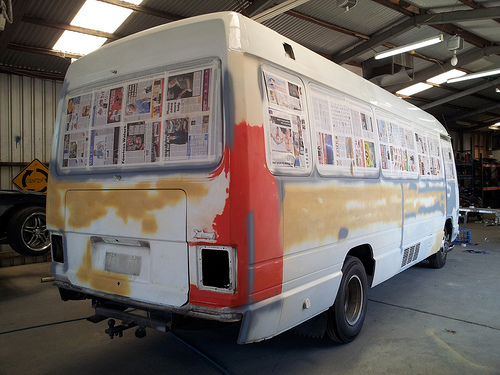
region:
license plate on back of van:
[98, 241, 154, 288]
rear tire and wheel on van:
[328, 239, 379, 351]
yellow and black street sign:
[11, 148, 66, 203]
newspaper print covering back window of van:
[58, 77, 239, 185]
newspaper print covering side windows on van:
[251, 58, 474, 203]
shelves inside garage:
[448, 116, 499, 207]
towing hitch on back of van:
[79, 298, 179, 354]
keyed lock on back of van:
[98, 160, 138, 198]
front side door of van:
[432, 106, 469, 256]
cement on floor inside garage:
[392, 281, 485, 373]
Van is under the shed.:
[45, 51, 437, 321]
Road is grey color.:
[387, 299, 464, 369]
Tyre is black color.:
[316, 253, 375, 348]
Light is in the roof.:
[359, 31, 496, 95]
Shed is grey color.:
[4, 26, 67, 152]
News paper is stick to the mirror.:
[61, 76, 437, 185]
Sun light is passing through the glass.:
[38, 6, 158, 59]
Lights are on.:
[364, 16, 499, 101]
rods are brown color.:
[325, 10, 497, 101]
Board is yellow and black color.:
[13, 152, 56, 199]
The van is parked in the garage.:
[52, 20, 464, 315]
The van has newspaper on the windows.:
[272, 98, 414, 163]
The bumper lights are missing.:
[168, 233, 249, 300]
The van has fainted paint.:
[83, 159, 451, 275]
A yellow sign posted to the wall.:
[11, 155, 56, 200]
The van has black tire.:
[323, 254, 393, 349]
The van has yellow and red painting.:
[276, 188, 414, 230]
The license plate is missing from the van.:
[83, 241, 158, 281]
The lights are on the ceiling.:
[36, 1, 461, 73]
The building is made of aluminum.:
[301, 7, 446, 66]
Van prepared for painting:
[41, 15, 470, 340]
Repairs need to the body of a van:
[205, 119, 290, 318]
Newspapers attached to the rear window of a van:
[53, 58, 229, 173]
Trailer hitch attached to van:
[92, 306, 141, 346]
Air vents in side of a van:
[396, 235, 428, 270]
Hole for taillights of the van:
[188, 241, 240, 295]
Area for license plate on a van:
[85, 230, 164, 284]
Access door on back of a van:
[55, 181, 197, 313]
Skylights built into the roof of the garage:
[37, 0, 165, 65]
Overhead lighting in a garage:
[361, 18, 445, 65]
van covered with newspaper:
[16, 17, 449, 330]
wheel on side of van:
[327, 262, 369, 337]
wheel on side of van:
[422, 230, 452, 272]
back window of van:
[68, 84, 220, 167]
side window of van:
[253, 80, 308, 180]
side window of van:
[308, 99, 373, 170]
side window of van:
[378, 120, 416, 178]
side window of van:
[412, 135, 442, 176]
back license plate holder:
[94, 253, 145, 281]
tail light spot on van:
[195, 242, 231, 290]